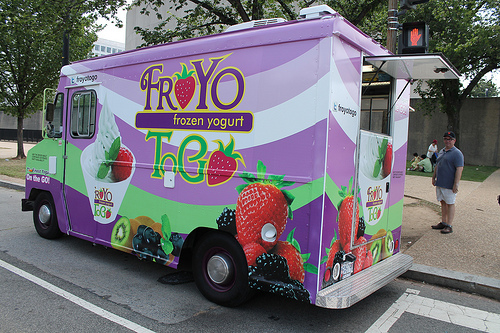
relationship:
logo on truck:
[136, 51, 254, 188] [20, 12, 462, 311]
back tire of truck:
[189, 232, 251, 303] [20, 12, 462, 311]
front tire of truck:
[33, 194, 61, 240] [20, 12, 462, 311]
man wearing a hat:
[433, 131, 463, 235] [443, 133, 457, 142]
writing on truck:
[173, 113, 245, 131] [20, 12, 462, 311]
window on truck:
[71, 91, 99, 137] [20, 12, 462, 311]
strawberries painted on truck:
[235, 165, 312, 281] [20, 12, 462, 311]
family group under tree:
[409, 139, 437, 173] [316, 1, 498, 162]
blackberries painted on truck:
[248, 255, 313, 303] [20, 12, 462, 311]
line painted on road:
[0, 259, 154, 332] [0, 185, 500, 332]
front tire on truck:
[33, 194, 61, 240] [20, 12, 462, 311]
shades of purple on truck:
[79, 22, 332, 203] [20, 12, 462, 311]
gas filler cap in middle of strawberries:
[260, 222, 277, 246] [235, 182, 304, 285]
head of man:
[444, 133, 456, 150] [433, 131, 463, 235]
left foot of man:
[433, 200, 446, 230] [433, 131, 463, 235]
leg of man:
[443, 200, 454, 234] [433, 131, 463, 235]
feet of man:
[435, 201, 458, 233] [433, 131, 463, 235]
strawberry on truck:
[207, 135, 243, 187] [20, 12, 462, 311]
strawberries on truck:
[235, 182, 304, 285] [20, 12, 462, 311]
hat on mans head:
[443, 133, 457, 142] [444, 133, 456, 150]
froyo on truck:
[83, 91, 134, 224] [20, 12, 462, 311]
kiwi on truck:
[110, 219, 130, 249] [20, 12, 462, 311]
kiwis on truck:
[371, 234, 395, 262] [20, 12, 462, 311]